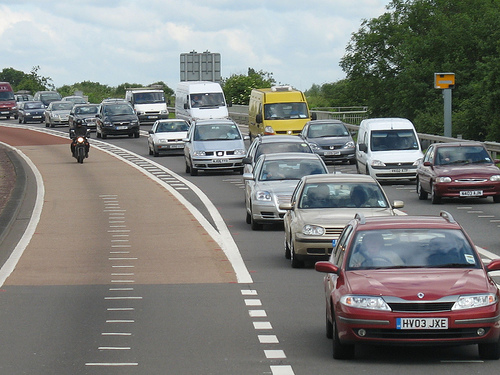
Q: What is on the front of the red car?
A: License plate.